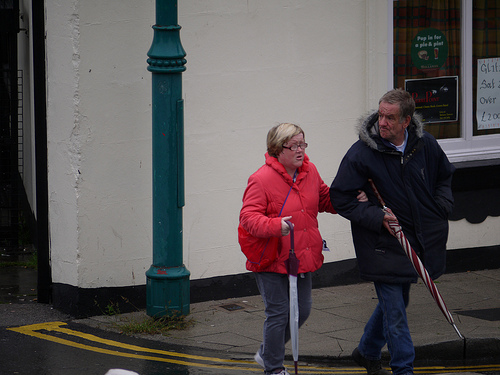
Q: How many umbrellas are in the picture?
A: Two.